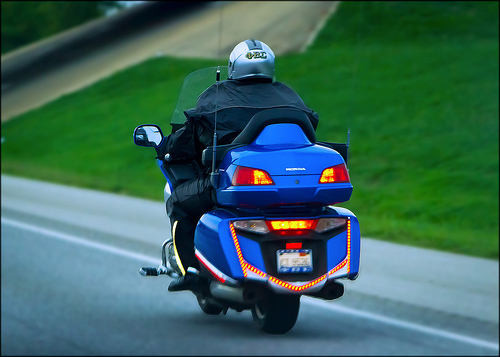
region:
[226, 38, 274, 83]
the man is wearing a helmet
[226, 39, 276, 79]
the helmet is made of plastic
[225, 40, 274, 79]
the helmet is shiny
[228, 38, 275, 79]
the helmet has a metallic look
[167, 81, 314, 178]
the man is wearing a jacket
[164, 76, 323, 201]
the jacket is black in color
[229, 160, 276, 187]
the backlight is turned on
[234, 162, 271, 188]
the light is red in color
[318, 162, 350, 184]
the light is red in colo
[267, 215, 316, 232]
the light is red in colo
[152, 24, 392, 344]
motorcycle on the road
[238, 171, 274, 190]
light on the motorcycle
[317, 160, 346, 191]
light on the motorcycle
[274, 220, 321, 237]
light on the motorcycle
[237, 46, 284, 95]
helmet on the rider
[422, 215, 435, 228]
patch of green grass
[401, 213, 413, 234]
patch of green grass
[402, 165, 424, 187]
patch of green grass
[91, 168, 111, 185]
patch of green grass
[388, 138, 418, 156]
patch of green grass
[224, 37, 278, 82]
silver helmet on a person's head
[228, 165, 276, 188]
red and orange motorcyle light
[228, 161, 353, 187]
two back motorcycle lights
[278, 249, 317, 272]
motorcycle license plate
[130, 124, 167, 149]
rearview mirror of a motorcyle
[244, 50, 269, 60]
back design on a silver helmet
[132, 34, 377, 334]
person riding a blue motorcycle on a street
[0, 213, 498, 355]
white line on a street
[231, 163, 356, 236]
three lights on the back of a motorcycle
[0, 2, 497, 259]
large green patch of grass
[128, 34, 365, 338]
Person riding a motorbike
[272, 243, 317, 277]
A white license plate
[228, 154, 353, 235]
Three red rear lights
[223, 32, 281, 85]
The helmet is silver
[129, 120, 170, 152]
Reflection in a side mirror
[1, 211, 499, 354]
White line on the road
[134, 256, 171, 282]
Pedal on the motorbike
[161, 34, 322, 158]
Rider wearing a black jacket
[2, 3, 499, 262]
Green grass on a hill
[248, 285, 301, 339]
A black round tire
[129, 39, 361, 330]
a man riding a motorcycle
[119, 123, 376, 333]
a blue motorcycle going down the street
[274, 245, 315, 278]
the license plate on a motorcycle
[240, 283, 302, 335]
the rear wheel of a motorcyle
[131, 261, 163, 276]
the footrest of a motorcyle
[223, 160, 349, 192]
the brake-lights of a motorcyle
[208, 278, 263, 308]
the muffler of a motorcyle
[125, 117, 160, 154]
the mirror of a motorcyle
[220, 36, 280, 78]
a silver and blue helmet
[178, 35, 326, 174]
a man wearing a silver and blue helmet